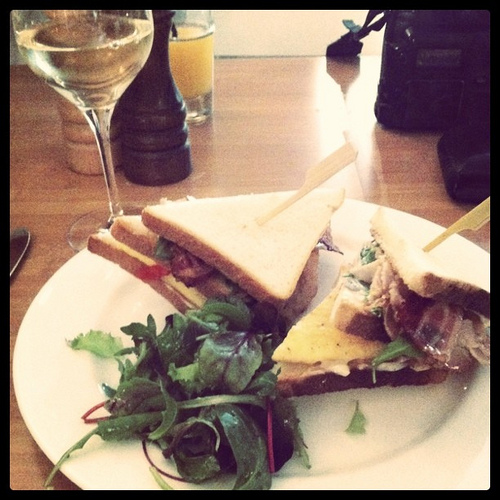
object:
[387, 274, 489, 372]
bacon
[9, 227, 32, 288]
knife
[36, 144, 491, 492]
dinner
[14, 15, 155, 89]
wine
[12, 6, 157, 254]
glass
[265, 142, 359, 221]
toothpick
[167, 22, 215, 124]
glass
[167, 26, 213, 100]
orange drink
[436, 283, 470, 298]
brown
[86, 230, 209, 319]
bread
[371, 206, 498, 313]
bread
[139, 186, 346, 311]
bread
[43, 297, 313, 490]
salad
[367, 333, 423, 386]
leaf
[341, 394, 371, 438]
leaf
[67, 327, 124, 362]
leaf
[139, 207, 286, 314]
brown crust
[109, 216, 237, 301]
bread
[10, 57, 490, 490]
table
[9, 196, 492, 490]
dinner plate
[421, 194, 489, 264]
toothpick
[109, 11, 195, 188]
pepper grinder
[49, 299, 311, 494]
vegetables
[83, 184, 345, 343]
sandwich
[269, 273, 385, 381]
cheese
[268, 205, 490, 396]
sandwich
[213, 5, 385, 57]
wall